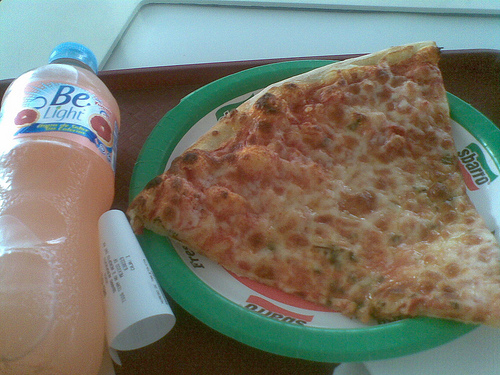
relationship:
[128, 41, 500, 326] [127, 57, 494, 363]
pizza on top of plate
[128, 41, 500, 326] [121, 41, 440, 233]
pizza has crust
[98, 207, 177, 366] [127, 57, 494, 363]
receipt next to plate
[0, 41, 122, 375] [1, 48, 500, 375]
bottle laying on tray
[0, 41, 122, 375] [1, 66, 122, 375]
bottle contains beverage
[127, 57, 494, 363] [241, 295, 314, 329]
plate has logo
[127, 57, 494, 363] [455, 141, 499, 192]
plate has logo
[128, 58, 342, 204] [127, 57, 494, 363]
rim next to plate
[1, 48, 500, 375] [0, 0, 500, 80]
tray on table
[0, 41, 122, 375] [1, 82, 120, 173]
bottle has label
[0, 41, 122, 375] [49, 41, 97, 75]
bottle has cap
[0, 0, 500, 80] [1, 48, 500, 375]
table under tray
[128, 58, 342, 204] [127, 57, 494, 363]
rim under plate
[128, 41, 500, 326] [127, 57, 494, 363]
pizza covers plate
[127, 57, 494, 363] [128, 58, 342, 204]
plate has rim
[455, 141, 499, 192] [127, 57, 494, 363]
logo on plate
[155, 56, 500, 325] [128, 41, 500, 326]
cheese covers pizza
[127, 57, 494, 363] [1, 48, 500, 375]
plate on tray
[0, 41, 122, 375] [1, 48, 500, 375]
bottle on tray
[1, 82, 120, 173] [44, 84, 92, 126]
label has logo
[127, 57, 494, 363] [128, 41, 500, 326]
plate under pizza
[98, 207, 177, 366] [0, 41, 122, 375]
receipt next to bottle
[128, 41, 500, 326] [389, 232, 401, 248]
pizza has oregano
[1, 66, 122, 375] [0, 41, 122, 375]
beverage in bottle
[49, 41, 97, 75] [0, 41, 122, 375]
cap on bottle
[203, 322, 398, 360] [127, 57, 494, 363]
edge of plate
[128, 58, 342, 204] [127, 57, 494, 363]
rim of plate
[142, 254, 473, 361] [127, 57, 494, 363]
edge of plate